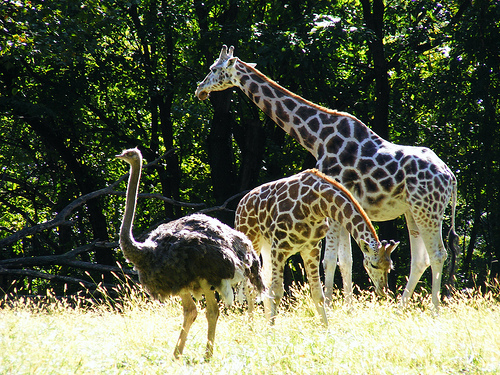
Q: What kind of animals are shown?
A: Giraffe and ostrich.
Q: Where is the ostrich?
A: In the grass.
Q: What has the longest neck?
A: The giraffes.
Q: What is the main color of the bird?
A: Brown.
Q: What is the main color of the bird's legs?
A: Brown.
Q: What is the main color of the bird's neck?
A: Brown.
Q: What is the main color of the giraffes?
A: Brown.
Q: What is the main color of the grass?
A: Green.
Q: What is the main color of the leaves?
A: Green.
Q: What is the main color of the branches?
A: Brown.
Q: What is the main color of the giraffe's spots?
A: Brown.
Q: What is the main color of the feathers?
A: Brown.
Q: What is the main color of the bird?
A: Brown.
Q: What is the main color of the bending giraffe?
A: Brown.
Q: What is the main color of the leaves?
A: Green.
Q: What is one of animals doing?
A: Grazing.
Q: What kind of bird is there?
A: An ostrich.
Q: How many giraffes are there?
A: Two.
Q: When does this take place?
A: Daytime.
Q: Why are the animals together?
A: To share a field.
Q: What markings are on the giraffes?
A: Large spots.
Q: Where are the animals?
A: In a field.